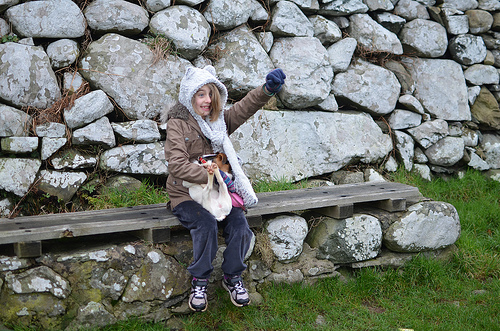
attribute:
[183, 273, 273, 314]
shoes — white, purple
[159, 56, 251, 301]
girl — sitting, smiling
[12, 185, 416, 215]
bench — wood, brown, wooden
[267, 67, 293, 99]
glove — blue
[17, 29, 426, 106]
rocks — stacked, rock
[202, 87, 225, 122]
hair — blond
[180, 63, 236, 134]
hat — white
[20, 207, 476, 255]
rocks — white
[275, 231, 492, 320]
grass — green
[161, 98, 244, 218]
coat — brown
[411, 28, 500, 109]
rocks — gray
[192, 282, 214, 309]
laces — white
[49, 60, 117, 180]
grass — brown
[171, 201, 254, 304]
pants — blue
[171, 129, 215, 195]
sleeves — brown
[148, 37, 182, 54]
grass — dead